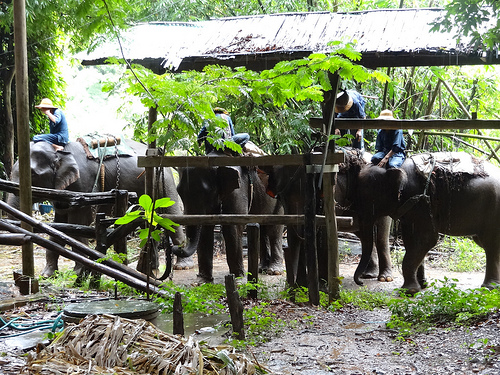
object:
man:
[33, 97, 69, 151]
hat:
[375, 109, 396, 120]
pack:
[76, 131, 135, 162]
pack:
[409, 150, 489, 180]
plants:
[101, 44, 392, 156]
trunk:
[353, 207, 375, 286]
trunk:
[173, 197, 206, 257]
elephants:
[0, 129, 499, 295]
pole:
[12, 0, 35, 279]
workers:
[371, 109, 408, 171]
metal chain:
[110, 140, 121, 218]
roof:
[81, 6, 496, 68]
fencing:
[133, 111, 497, 281]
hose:
[0, 309, 65, 353]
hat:
[334, 89, 354, 113]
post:
[144, 103, 158, 226]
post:
[299, 152, 318, 305]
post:
[323, 87, 339, 306]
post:
[138, 150, 343, 167]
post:
[162, 213, 354, 222]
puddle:
[156, 308, 223, 333]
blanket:
[410, 150, 490, 179]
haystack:
[22, 303, 272, 374]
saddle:
[75, 130, 138, 160]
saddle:
[412, 148, 492, 186]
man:
[333, 89, 367, 150]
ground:
[4, 284, 475, 372]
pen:
[144, 101, 500, 307]